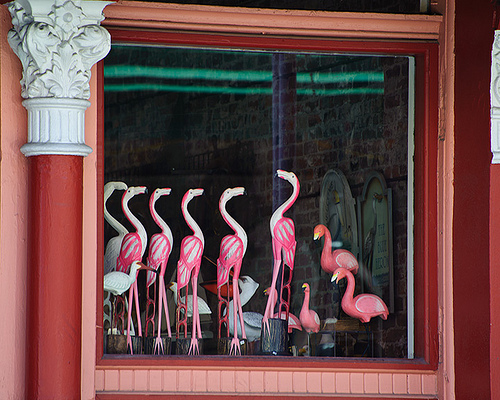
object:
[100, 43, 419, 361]
glass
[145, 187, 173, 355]
flamingo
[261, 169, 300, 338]
bird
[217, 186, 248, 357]
bird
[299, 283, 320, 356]
bird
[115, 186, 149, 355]
bird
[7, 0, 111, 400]
column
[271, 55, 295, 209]
red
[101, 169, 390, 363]
display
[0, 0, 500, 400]
bad statement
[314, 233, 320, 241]
beak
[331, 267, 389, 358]
bird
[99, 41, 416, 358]
window display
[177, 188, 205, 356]
flamingo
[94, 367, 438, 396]
brick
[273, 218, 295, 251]
wing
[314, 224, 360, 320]
bird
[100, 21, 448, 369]
window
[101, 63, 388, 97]
reflection